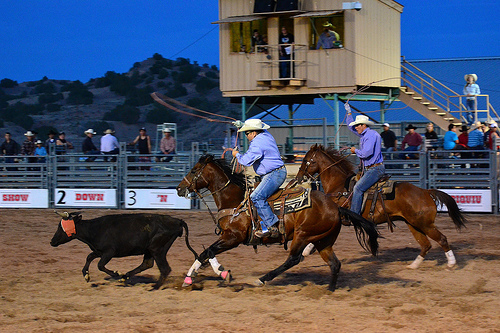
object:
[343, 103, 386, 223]
cowboy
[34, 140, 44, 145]
hat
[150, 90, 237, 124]
lasso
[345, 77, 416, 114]
lasso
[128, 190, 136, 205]
number 3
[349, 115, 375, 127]
hat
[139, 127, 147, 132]
hat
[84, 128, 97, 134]
hat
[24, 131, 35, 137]
hat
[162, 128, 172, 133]
hat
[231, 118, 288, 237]
cowboy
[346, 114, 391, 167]
shirt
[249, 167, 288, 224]
pants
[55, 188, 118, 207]
sign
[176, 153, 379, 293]
brown horse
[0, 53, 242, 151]
mountain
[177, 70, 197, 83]
trees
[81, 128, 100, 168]
person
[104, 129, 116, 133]
hat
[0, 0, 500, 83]
sky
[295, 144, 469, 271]
horse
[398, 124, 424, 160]
man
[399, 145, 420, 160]
blue jeans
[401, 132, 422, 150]
red shirt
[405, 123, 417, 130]
black hat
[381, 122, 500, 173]
bleachers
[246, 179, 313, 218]
saddle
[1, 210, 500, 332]
dirt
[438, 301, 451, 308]
footprint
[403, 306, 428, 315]
footprint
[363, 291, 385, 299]
footprint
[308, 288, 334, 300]
footprint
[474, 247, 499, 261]
footprint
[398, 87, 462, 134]
railings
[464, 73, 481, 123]
woman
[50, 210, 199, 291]
black calf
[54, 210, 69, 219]
horns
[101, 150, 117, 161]
pants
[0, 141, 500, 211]
fence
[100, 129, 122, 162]
man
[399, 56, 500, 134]
stairs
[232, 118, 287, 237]
outfits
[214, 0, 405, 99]
box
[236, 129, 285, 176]
blue shirt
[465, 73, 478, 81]
white hat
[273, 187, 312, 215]
blanket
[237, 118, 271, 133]
hat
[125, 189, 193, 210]
white background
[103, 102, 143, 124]
green bush